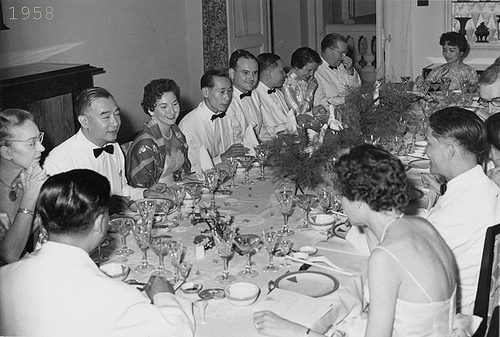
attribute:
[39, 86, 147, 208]
person — having food, eating food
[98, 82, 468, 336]
table cloth — white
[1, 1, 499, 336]
picture — black, white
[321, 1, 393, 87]
door — open, doorway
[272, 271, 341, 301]
plate — white, empty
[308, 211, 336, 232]
bowl — white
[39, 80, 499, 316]
table — existing, decorated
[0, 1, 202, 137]
wall — existing, in photo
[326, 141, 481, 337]
person — having dinner, resting hand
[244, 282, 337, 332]
paper — a piece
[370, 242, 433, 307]
string — existing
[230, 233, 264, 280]
glass — existing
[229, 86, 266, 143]
jacket — white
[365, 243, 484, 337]
dress — white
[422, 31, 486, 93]
woman — sitting, smiling